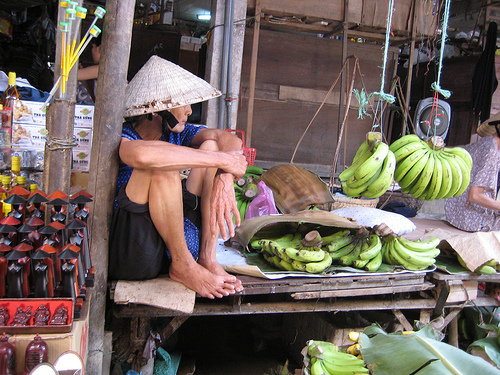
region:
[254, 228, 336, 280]
bunch of green bananas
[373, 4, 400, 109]
green rope hanging from ceiling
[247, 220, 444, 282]
bunches of green bananas on table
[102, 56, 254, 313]
man setting on counter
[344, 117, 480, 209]
bunches of bananas hanging from rope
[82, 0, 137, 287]
large wooden roof support post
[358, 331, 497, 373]
large green banana tree leaf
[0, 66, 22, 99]
top of glass bottle behind boxes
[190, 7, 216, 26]
light on ceiling inside building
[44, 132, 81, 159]
rope tied around wooden post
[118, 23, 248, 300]
this is a man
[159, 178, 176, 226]
the man is light sklinned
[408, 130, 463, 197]
this is a bunch of banana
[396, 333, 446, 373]
this is the leaf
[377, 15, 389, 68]
the rope is blue in color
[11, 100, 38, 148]
this is a box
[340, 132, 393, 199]
a bunch of bananas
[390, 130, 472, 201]
a bunch of bananas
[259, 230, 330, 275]
a bunch of bananas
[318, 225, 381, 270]
a bunch of bananas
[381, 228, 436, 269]
a bunch of bananas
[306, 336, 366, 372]
a bunch of bananas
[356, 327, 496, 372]
a large green banana leaf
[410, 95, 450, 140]
an electric fan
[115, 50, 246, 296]
a person sitting on table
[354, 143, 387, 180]
a green banana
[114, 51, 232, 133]
hat on the head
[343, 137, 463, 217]
the bananas are hanging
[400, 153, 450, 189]
the bananas are unripe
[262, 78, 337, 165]
the wall is wood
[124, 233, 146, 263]
the outfit is black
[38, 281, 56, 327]
drinks in the box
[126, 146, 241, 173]
arm of the woman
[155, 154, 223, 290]
leg of the woman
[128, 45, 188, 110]
the hat is bamboo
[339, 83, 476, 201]
Two branches of bananas hanging from strings.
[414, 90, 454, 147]
Scale for weighing fruit.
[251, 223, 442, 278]
Three batches of bananas on wooden table.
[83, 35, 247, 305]
Man leaning against wooden post.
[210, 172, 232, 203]
Veins cascading down man's hand.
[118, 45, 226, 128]
Conical hat providing shade for man.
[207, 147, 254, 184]
Right hand grasping left wrist.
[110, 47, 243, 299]
Man in blue top and black shorts.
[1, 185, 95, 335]
Red and black idols on table.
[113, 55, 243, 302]
man wearing a hat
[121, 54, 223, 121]
hat is straw and cone-shaped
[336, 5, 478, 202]
bananas hanging from string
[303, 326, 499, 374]
banana leaf on top of bananas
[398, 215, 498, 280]
brown paper covering bananas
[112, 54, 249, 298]
man wearing blue shirt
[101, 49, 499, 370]
man sitting on top of fruit stand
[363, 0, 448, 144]
yarn strings are green and red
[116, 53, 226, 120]
person wearing protective covering on head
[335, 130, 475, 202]
two bunches of green bananas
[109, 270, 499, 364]
old wooden tables with fruit on top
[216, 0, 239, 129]
two pipes running up beam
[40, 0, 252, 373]
several wooden support beams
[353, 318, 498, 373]
large green banana leaves covering bananas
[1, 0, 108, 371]
miscellaneous items sold at market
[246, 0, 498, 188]
wooden background to building unit